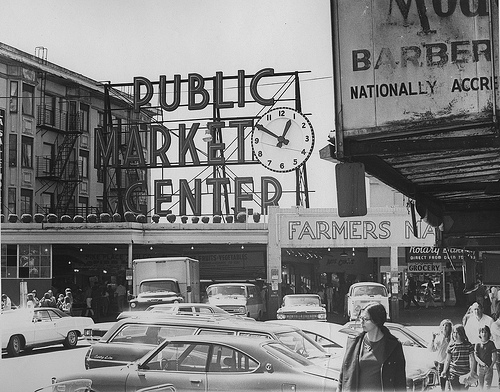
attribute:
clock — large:
[251, 106, 315, 171]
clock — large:
[246, 97, 323, 182]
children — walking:
[433, 301, 498, 383]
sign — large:
[88, 73, 298, 220]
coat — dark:
[339, 329, 409, 389]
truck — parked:
[130, 258, 198, 300]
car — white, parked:
[1, 297, 96, 355]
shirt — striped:
[446, 340, 473, 371]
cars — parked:
[50, 305, 340, 384]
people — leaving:
[331, 292, 499, 389]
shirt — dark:
[356, 329, 385, 389]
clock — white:
[242, 107, 322, 171]